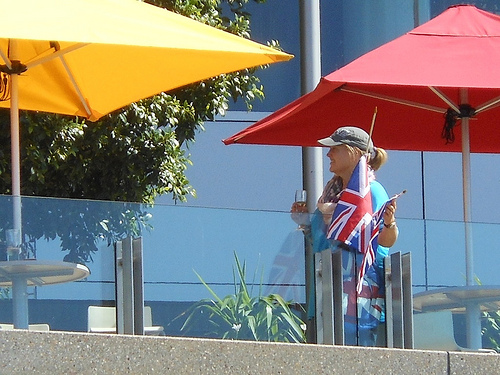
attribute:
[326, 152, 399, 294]
flags — british, red,white,blue, united kingdom, union jack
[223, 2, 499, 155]
umbrella — red, large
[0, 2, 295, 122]
umbrella — yellow, large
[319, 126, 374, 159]
baseball cap — gray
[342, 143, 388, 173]
hair — blonde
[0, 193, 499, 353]
barrier — made of glass, glass, a railing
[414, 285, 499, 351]
table — small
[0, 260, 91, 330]
table — small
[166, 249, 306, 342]
plant — green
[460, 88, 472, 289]
pole — white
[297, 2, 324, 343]
post — metal, tall, a support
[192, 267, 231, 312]
leaf — green